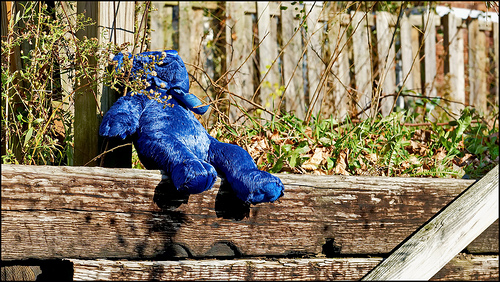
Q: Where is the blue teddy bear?
A: On the wooden board.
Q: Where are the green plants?
A: In front of the fence.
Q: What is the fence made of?
A: Wood.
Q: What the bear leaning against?
A: A wooden post.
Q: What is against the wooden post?
A: The teddy bear.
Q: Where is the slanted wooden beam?
A: Against the wall.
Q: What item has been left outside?
A: The teddy bear.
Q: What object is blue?
A: The teddy bear.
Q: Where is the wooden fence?
A: Behind the teddy bear.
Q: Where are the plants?
A: Behind the teddy bear.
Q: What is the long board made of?
A: Wood.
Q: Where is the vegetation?
A: In front of the fence.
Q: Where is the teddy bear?
A: On the wooden board.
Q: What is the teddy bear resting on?
A: The fence post.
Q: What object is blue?
A: The teddy bear.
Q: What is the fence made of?
A: Wood.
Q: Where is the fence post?
A: Behind the teddy bear.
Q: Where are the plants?
A: Behind the wooden boards.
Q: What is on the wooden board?
A: A stuffed toy.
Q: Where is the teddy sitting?
A: On the wood.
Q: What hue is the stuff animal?
A: Blue.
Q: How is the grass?
A: Brown and green.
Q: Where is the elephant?
A: In a park.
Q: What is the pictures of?
A: A stuffed animal.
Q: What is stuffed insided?
A: The elephant.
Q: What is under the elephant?
A: The log.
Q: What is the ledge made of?
A: Wood.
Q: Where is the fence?
A: Behind elephant.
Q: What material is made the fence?
A: Wood.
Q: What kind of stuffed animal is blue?
A: A bear.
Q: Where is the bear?
A: Against the fence.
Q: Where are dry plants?
A: Next the fence.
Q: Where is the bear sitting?
A: On wooden object.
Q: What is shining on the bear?
A: The sun.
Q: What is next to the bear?
A: Plants.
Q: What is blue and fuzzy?
A: Stuffed toy.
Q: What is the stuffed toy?
A: Blue bear.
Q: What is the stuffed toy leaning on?
A: Wood post.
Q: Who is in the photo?
A: No one.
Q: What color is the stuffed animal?
A: Blue.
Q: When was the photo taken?
A: During the day.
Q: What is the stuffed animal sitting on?
A: Wooden railroad ties.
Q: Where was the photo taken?
A: Along a fence.